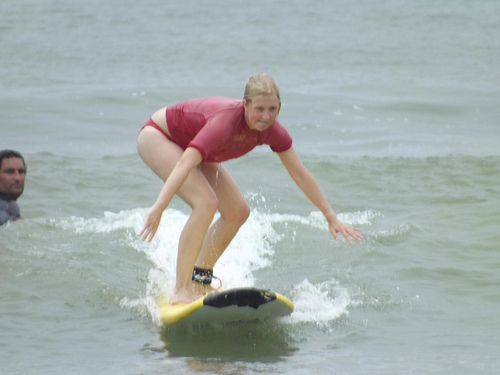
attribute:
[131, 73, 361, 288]
girl — surfing, barefoot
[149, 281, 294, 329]
surfboard — yellow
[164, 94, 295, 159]
shirt — red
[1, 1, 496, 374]
ocean — small rippled, rippled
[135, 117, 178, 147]
bathing suit — red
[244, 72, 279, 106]
hair — wet, blond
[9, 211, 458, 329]
wave — small